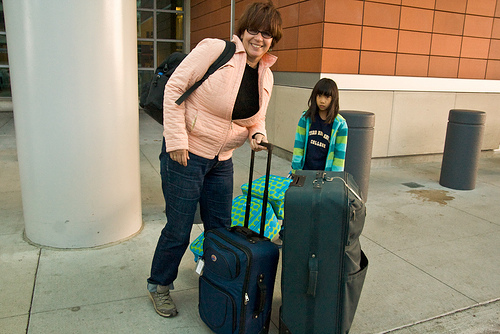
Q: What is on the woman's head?
A: Her hair.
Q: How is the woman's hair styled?
A: Short cut.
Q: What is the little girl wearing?
A: A tri color hoody.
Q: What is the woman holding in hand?
A: Black suitcase.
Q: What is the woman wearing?
A: Peach jacket.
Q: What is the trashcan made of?
A: Metal.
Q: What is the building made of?
A: Orange bricks.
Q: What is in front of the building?
A: White column.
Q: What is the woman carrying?
A: A black backpack.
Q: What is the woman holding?
A: A blue and black suitcase.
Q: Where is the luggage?
A: In front of the woman.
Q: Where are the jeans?
A: On the woman.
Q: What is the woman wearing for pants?
A: Jeans.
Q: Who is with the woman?
A: The little girl.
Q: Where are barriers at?
A: Behind the girl.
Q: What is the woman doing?
A: Smiling for the camera.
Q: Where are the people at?
A: The airport.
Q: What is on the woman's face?
A: Glasses.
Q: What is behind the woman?
A: A large column.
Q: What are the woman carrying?
A: 2 pieces of luggage.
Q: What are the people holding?
A: Suitcases.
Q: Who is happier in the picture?
A: The older woman.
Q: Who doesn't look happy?
A: The child.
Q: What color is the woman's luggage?
A: Blue.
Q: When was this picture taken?
A: Daytime.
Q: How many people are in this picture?
A: Two.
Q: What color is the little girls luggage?
A: Blue and green.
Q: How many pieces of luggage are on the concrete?
A: Three.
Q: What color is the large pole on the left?
A: White.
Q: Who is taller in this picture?
A: The woman.